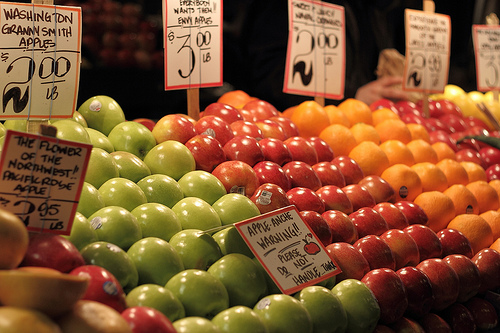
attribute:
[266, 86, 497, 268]
oranges — in the picture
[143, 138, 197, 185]
apples — green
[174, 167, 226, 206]
apples — green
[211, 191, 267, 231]
apples — green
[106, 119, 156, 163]
apples — green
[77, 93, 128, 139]
apples — green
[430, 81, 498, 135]
bananas — yellow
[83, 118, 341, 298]
apples — green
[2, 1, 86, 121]
paper — in the picture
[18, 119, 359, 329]
apples — green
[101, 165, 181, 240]
smith apples — Washington Grammy 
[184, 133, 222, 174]
apple — red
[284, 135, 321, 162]
apple — red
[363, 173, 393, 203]
apple — red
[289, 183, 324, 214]
apple — red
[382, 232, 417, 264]
apple — red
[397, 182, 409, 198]
sticker — oval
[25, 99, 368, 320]
apples — green